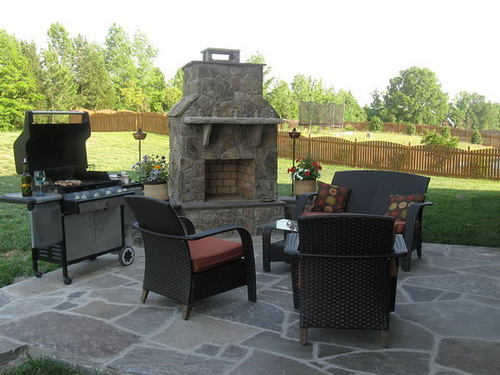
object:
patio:
[0, 0, 499, 374]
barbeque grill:
[0, 110, 146, 284]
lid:
[12, 110, 90, 174]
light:
[287, 126, 301, 139]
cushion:
[187, 235, 242, 271]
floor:
[0, 233, 499, 374]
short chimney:
[167, 47, 287, 120]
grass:
[0, 130, 499, 286]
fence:
[69, 107, 500, 180]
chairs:
[121, 193, 258, 319]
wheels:
[117, 244, 135, 266]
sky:
[0, 0, 499, 108]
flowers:
[301, 170, 309, 176]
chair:
[283, 212, 406, 348]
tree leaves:
[416, 90, 420, 94]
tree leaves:
[16, 69, 18, 72]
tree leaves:
[431, 138, 438, 141]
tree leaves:
[155, 77, 160, 78]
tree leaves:
[274, 88, 281, 92]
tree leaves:
[150, 70, 156, 75]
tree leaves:
[2, 91, 7, 100]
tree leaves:
[84, 71, 87, 73]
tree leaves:
[456, 97, 461, 101]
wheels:
[62, 275, 73, 284]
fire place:
[168, 47, 283, 239]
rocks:
[199, 77, 219, 100]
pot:
[293, 178, 318, 195]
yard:
[0, 130, 497, 373]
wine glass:
[33, 169, 45, 197]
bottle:
[20, 158, 32, 198]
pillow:
[310, 180, 352, 212]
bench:
[293, 169, 435, 271]